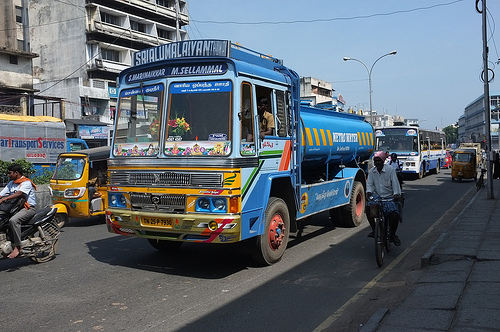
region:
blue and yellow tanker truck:
[102, 40, 375, 262]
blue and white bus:
[378, 127, 444, 175]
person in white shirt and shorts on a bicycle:
[362, 152, 403, 267]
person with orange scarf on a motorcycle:
[1, 167, 59, 268]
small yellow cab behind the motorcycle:
[51, 154, 107, 229]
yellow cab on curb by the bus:
[451, 145, 476, 180]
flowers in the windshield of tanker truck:
[147, 115, 190, 140]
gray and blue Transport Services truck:
[0, 120, 87, 173]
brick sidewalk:
[377, 170, 499, 327]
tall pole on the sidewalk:
[476, 3, 497, 195]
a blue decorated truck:
[112, 43, 354, 253]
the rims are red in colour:
[256, 209, 304, 262]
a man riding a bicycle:
[361, 145, 408, 257]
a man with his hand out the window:
[256, 81, 275, 141]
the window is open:
[258, 88, 276, 133]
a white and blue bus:
[374, 129, 436, 166]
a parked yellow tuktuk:
[444, 150, 480, 177]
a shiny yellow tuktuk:
[58, 145, 106, 211]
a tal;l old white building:
[46, 3, 116, 85]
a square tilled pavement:
[435, 214, 499, 322]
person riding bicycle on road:
[312, 140, 487, 330]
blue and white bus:
[377, 110, 468, 189]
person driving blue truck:
[172, 52, 372, 283]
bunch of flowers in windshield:
[138, 66, 241, 157]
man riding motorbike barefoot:
[7, 159, 87, 269]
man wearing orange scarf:
[4, 147, 67, 287]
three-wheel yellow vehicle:
[42, 142, 125, 239]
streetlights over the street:
[330, 33, 429, 159]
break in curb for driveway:
[299, 205, 498, 330]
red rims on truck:
[199, 92, 343, 293]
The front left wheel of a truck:
[245, 192, 296, 274]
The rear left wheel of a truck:
[343, 174, 368, 230]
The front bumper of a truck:
[98, 203, 243, 248]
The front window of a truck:
[105, 79, 239, 166]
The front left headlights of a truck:
[193, 188, 236, 218]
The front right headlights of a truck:
[102, 186, 130, 213]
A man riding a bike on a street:
[357, 145, 414, 264]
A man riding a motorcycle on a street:
[3, 151, 69, 268]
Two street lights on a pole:
[338, 45, 410, 137]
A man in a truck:
[253, 100, 283, 145]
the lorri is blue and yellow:
[127, 39, 377, 257]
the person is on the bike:
[353, 155, 413, 260]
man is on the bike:
[6, 168, 60, 275]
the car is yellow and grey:
[56, 144, 110, 224]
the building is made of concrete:
[36, 2, 108, 116]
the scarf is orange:
[14, 173, 46, 215]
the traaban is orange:
[373, 144, 391, 161]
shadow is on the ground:
[98, 240, 225, 296]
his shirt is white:
[363, 164, 401, 191]